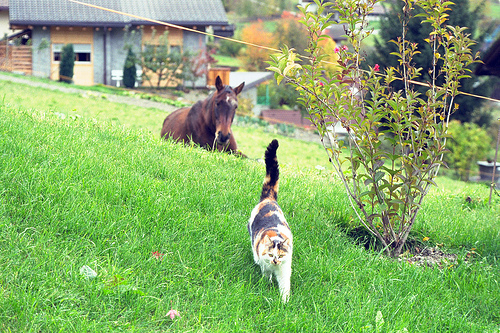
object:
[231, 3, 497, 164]
blurry trees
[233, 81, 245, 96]
ear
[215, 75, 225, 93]
ear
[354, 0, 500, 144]
tree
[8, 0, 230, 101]
house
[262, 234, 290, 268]
head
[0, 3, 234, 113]
building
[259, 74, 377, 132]
ground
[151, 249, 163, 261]
flower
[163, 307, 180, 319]
flower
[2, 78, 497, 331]
lawn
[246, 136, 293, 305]
cat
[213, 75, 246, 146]
head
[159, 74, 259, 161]
horse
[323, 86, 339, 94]
leaves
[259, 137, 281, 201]
tail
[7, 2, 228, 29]
roof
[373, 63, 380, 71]
flower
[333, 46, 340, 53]
flower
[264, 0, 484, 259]
shrub/bush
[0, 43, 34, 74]
fence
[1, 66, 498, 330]
grass